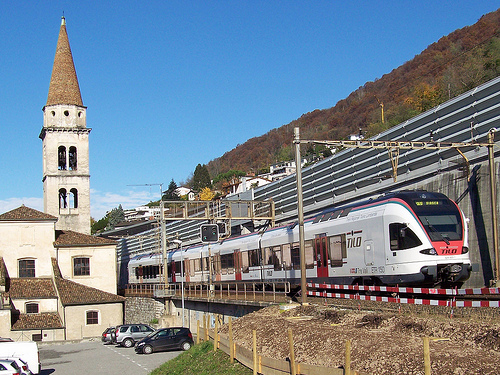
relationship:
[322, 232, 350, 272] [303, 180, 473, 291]
window on train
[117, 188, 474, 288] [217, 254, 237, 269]
train has window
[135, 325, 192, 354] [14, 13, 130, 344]
car parked near church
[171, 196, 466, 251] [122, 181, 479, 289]
red stripe on train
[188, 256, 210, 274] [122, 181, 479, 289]
window of train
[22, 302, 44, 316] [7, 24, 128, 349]
window on building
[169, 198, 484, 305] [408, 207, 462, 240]
train has windshield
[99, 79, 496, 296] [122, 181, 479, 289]
building near train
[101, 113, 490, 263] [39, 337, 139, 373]
lines on ground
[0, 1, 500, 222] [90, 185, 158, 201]
sky with clouds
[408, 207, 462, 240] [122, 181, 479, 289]
windshield on train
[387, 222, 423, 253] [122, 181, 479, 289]
window on train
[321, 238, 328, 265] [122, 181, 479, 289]
window on train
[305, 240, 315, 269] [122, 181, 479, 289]
window on train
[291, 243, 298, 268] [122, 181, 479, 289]
window on train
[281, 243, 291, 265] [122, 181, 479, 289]
window on train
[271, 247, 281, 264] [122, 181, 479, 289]
window on train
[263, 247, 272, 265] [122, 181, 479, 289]
window on train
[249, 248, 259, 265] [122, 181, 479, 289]
window on train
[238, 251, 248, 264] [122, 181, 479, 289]
window on train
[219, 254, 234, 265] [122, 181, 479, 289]
window on train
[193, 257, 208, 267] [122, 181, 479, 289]
window on train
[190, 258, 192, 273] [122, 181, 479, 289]
window on train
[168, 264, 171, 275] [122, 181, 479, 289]
window on train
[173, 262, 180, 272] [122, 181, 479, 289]
window on train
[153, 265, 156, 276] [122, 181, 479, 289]
window on train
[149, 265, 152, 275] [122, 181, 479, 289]
window on train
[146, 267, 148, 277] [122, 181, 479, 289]
window on train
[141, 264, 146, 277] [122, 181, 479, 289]
window on train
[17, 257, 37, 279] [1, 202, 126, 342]
window on building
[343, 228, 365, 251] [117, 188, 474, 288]
logo on side of train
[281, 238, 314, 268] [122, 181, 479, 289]
window of train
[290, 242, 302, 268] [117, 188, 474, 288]
window on train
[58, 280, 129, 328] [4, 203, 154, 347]
window on building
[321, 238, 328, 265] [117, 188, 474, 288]
window on train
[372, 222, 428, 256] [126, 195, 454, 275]
window on a train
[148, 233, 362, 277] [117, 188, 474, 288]
windows on train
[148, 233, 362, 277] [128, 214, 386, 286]
windows on right side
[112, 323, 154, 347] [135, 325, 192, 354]
car parked next to car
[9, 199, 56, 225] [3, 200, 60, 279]
roof on top of building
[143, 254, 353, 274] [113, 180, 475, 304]
windows on train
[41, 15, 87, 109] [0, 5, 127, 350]
steeple on church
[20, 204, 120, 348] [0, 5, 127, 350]
wall of church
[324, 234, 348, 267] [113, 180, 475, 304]
window of train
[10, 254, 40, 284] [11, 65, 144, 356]
window on building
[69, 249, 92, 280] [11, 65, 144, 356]
window on building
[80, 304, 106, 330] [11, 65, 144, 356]
window on building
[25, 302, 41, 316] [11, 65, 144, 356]
window on building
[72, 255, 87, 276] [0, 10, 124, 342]
window on building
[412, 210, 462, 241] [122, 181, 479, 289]
window on train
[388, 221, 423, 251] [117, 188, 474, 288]
window on train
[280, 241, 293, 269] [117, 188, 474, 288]
window on train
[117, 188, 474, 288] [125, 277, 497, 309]
train sitting on tracks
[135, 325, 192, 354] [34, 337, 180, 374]
car in ground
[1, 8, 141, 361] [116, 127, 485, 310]
building on side of road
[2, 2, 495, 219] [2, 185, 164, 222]
sky with clouds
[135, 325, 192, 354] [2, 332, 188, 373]
car parked in lot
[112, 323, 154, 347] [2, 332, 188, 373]
car parked in lot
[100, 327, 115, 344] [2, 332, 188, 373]
car parked in lot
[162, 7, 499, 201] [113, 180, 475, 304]
mountain near train